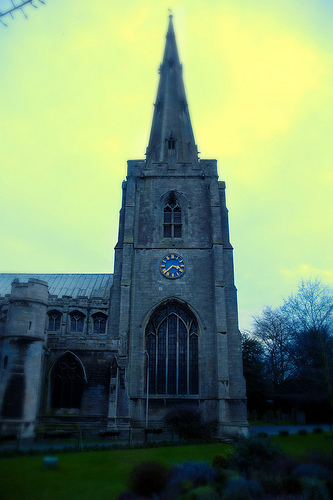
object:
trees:
[240, 333, 269, 424]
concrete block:
[128, 398, 146, 423]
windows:
[163, 221, 173, 239]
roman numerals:
[160, 262, 166, 269]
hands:
[162, 263, 174, 276]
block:
[214, 285, 228, 333]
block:
[119, 241, 135, 289]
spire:
[144, 9, 200, 172]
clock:
[157, 249, 186, 282]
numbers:
[170, 253, 174, 261]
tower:
[105, 9, 251, 448]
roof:
[0, 272, 114, 307]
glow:
[0, 0, 333, 344]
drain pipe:
[145, 349, 150, 428]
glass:
[166, 313, 178, 396]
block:
[216, 332, 229, 381]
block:
[211, 242, 225, 287]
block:
[209, 205, 223, 250]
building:
[0, 14, 251, 440]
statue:
[164, 5, 177, 16]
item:
[41, 456, 59, 470]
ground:
[0, 414, 333, 499]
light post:
[145, 348, 150, 430]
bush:
[120, 458, 171, 500]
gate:
[0, 417, 181, 457]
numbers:
[171, 273, 174, 279]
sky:
[0, 0, 333, 362]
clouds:
[0, 0, 333, 354]